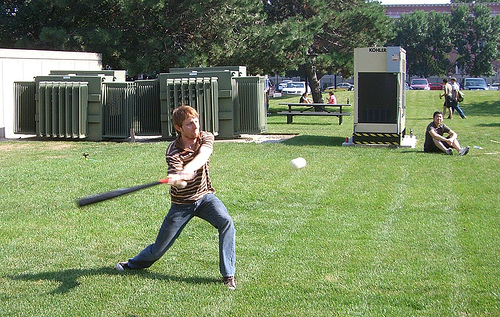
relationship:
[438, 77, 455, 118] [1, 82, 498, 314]
person walking on grass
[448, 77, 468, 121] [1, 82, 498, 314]
person walking on grass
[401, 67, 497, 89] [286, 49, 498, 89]
car in parking lot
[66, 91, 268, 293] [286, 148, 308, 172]
man swing ball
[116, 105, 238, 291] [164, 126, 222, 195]
man wears shirt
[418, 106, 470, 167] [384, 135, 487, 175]
man on grass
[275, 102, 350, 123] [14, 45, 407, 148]
picnic table by power boxes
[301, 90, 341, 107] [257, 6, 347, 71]
people by tree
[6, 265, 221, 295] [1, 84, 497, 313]
shadow on ground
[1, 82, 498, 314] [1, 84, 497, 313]
grass on ground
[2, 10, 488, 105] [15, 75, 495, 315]
trees in park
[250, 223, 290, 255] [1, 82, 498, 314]
patch on grass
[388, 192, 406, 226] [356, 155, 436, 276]
patch on grass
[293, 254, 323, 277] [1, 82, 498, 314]
patch on grass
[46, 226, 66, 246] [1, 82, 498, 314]
patch on grass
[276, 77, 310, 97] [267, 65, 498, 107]
car in parking lot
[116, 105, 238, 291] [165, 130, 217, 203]
man in striped shirt